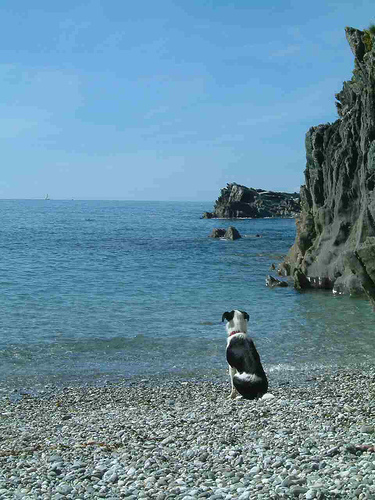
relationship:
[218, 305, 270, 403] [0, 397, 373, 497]
dog sitting on beach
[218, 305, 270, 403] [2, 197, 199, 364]
dog looking out to sea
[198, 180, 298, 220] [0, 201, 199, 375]
formation in water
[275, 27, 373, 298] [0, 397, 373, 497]
cliff at beach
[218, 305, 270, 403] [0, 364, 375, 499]
dog on rocks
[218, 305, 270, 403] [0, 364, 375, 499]
dog sitting on rocks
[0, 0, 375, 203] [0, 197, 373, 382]
sky above sea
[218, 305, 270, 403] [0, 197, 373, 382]
dog facing sea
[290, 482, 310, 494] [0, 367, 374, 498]
rocks on beach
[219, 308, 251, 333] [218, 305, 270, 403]
head on dog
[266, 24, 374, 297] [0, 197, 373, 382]
cliff-face in sea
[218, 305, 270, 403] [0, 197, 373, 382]
dog gazing at sea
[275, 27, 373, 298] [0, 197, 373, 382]
cliff jutting from sea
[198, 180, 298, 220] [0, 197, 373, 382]
formation jutting from sea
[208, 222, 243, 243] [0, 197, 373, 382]
rock jutting from sea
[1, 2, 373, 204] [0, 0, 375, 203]
clouds in sky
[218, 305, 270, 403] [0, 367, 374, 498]
dog on beach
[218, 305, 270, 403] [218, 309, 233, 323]
dog has ear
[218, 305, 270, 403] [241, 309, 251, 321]
dog has ear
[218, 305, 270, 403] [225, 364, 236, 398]
dog has leg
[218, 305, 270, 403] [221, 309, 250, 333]
dog has head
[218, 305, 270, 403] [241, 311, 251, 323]
dog has ear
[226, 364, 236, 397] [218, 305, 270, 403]
front leg on dog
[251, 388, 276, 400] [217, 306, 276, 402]
tail on dog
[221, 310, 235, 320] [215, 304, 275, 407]
ear on dog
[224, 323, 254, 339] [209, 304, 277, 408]
neck of dog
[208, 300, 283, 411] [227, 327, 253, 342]
dog has collar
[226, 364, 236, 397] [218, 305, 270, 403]
front leg of dog